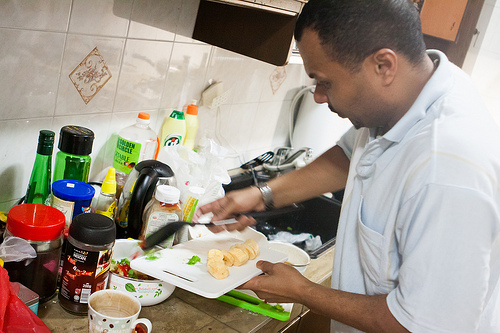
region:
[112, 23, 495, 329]
a man serving himself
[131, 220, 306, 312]
the plate is white in colour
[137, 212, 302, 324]
it is rectangular in shape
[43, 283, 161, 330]
the cup is white in colour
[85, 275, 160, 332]
it has a brown liquid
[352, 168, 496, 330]
the shirt is white in colour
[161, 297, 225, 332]
the table is wooden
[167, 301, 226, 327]
it is brown in colour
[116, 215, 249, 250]
the ladle is black in colour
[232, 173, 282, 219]
the man has a watch in his arm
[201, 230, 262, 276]
A sliced up banana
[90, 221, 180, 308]
A filled with fruits/greens/veggies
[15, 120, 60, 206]
A green bottle on the back of the counter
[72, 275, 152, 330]
An unwashed coffee mug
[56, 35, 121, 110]
A brown/gold design on the wall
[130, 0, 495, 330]
A man putting things into a bowl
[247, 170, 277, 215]
A silver wrist watch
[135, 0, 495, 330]
A man in a light blue T-shirt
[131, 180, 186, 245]
A bottle of ketchup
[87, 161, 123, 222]
A bottle of salad dressing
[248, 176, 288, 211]
silver watch on man's right wrist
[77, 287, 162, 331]
empty white spotted coffee mug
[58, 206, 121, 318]
instant coffee with dark lid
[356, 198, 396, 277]
white pocket on man's shirt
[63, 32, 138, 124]
gold design on white wall tile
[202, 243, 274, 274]
yellow sliced bananna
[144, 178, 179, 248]
ketchup bottle with white lid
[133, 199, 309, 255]
black spatula in man's right hand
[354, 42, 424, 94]
left ear on man's head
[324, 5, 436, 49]
dark black hair on man's head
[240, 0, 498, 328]
a man cooking in a kitchen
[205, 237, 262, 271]
food on a plate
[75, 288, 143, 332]
coffee cup on the counter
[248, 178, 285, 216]
watch on the man's wrist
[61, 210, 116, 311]
jar on the counter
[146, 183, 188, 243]
ketchup bottle on the counter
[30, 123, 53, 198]
green bottle on the counter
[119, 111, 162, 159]
bottle on the counter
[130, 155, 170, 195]
coffee pot on the counter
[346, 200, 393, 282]
pocket on the man's shirt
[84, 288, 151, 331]
empty dirty coffee mug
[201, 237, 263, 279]
bananas on plate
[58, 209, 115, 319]
brown plastic jar on counter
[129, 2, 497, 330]
man putting food in bowl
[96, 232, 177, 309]
bowl of cut vegetables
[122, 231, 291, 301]
white plastic chopping block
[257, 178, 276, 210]
watch on man's wrist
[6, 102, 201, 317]
various condiments on counter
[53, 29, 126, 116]
decorative wall tile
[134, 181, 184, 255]
almost empty bottle of catsup